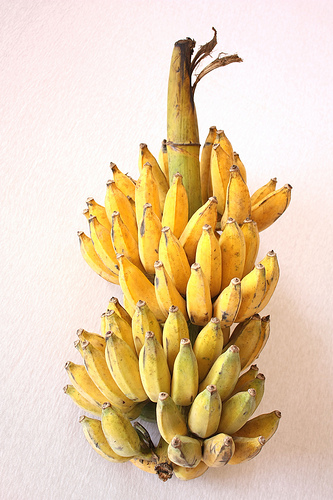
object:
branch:
[191, 53, 242, 101]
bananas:
[171, 337, 198, 406]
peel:
[252, 183, 294, 231]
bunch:
[64, 123, 292, 483]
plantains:
[63, 119, 295, 484]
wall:
[0, 0, 61, 500]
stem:
[164, 38, 203, 220]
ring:
[167, 142, 201, 147]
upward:
[84, 127, 291, 215]